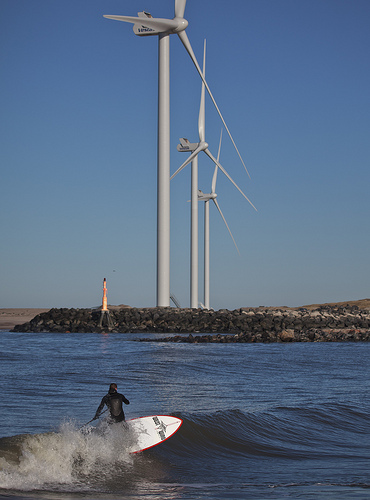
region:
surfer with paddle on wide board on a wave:
[83, 373, 249, 468]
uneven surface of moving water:
[131, 345, 353, 394]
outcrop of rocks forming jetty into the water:
[74, 320, 333, 348]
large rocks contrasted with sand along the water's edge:
[2, 293, 60, 338]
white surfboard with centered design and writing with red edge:
[106, 398, 200, 450]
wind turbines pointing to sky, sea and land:
[102, 5, 269, 351]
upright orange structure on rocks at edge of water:
[74, 266, 126, 335]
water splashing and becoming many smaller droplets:
[8, 415, 133, 483]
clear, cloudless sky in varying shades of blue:
[260, 15, 350, 282]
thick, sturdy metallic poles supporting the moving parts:
[121, 40, 216, 315]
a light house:
[90, 273, 115, 321]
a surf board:
[103, 403, 188, 475]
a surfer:
[88, 372, 137, 435]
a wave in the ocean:
[2, 388, 369, 498]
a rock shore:
[10, 298, 368, 343]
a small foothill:
[0, 304, 54, 330]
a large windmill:
[196, 122, 245, 308]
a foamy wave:
[0, 417, 142, 491]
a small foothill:
[247, 294, 369, 304]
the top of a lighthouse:
[97, 274, 107, 285]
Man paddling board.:
[71, 364, 192, 486]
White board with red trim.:
[136, 410, 183, 467]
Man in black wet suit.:
[89, 376, 132, 437]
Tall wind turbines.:
[120, 0, 292, 311]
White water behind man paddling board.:
[2, 413, 162, 495]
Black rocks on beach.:
[19, 295, 366, 357]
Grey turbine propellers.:
[174, 59, 267, 246]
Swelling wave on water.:
[191, 394, 355, 468]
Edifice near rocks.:
[96, 265, 119, 325]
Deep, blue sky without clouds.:
[10, 54, 123, 249]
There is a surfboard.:
[87, 380, 180, 462]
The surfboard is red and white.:
[80, 412, 197, 460]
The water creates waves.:
[1, 401, 367, 472]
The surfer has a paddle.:
[62, 407, 121, 433]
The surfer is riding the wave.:
[74, 376, 188, 464]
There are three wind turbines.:
[101, 5, 261, 309]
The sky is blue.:
[1, 1, 361, 291]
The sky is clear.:
[3, 6, 367, 308]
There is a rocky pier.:
[9, 302, 362, 346]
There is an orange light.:
[92, 272, 124, 337]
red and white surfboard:
[109, 407, 183, 458]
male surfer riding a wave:
[96, 382, 133, 424]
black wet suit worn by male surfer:
[100, 390, 135, 424]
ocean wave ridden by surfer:
[3, 418, 190, 479]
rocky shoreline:
[21, 302, 369, 333]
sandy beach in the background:
[0, 303, 43, 327]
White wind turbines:
[105, 6, 244, 310]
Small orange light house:
[96, 275, 109, 316]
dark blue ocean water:
[16, 335, 365, 407]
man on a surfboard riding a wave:
[84, 380, 182, 459]